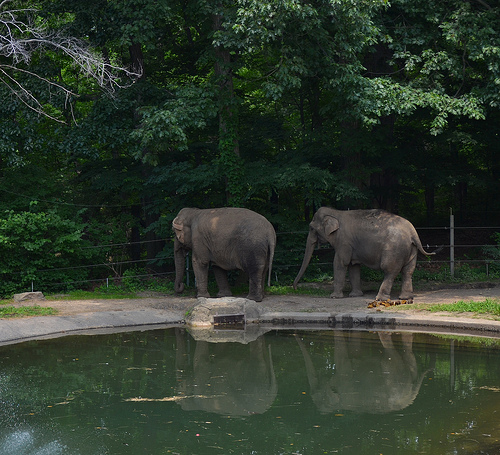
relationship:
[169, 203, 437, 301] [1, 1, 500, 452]
elephants in zoo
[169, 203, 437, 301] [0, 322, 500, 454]
elephants by pond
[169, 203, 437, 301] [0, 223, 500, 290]
elephants by fence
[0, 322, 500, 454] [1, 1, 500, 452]
pond in zoo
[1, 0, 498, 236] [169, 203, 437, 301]
trees behind elephants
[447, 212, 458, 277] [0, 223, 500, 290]
pole on fence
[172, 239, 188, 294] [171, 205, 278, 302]
trunk on elephant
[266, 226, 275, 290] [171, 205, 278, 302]
tail of elephant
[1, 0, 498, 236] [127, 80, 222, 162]
trees have leaves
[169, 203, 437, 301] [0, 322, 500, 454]
elephants near pond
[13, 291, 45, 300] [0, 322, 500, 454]
stone by pond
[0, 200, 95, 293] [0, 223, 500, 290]
bush behind fence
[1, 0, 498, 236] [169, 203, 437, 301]
trees by elephants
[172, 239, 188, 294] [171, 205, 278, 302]
trunk of elephant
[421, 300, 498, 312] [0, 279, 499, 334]
grass on ground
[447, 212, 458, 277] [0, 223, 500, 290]
pole holding fence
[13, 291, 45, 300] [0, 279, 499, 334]
stone on ground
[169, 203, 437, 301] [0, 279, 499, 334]
elephants on ground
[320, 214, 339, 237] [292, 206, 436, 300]
ears of elephant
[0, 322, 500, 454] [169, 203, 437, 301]
pond near elephants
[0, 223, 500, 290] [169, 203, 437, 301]
fence near elephants